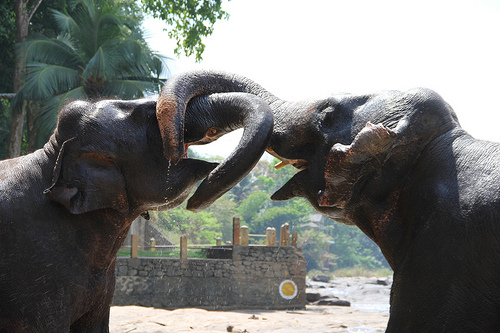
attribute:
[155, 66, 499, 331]
elephant — large, wet, gray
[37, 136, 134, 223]
ear — grey, big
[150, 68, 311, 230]
gray trunks — wet, large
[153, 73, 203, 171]
elephant tusk — short, yellow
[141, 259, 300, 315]
stone wall — gray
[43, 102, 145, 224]
ear — large, wet, gray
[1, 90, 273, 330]
elephant — gray, wet, large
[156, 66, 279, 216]
elephant trunk — gray, large, wet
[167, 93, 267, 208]
trunk — gray, wet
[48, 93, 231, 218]
head — big, grey